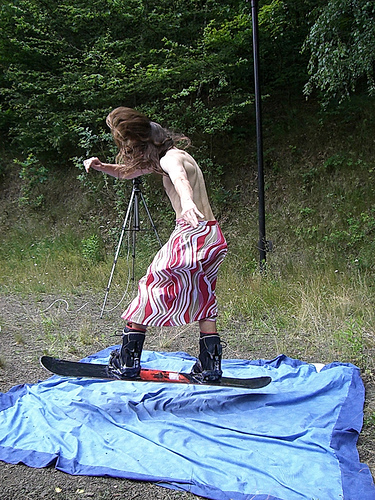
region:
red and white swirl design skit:
[134, 219, 231, 319]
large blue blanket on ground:
[8, 331, 369, 499]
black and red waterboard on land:
[39, 348, 271, 390]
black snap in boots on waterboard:
[109, 325, 229, 379]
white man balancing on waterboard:
[82, 103, 228, 386]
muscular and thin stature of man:
[80, 140, 222, 232]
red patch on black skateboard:
[139, 367, 188, 386]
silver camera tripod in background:
[96, 171, 166, 316]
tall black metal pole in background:
[246, 0, 277, 279]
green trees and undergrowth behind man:
[2, 0, 370, 342]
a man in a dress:
[64, 82, 373, 398]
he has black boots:
[12, 270, 291, 440]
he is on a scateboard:
[12, 304, 254, 428]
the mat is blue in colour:
[14, 303, 369, 499]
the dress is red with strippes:
[141, 196, 259, 346]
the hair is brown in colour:
[62, 79, 209, 196]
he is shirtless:
[122, 158, 228, 221]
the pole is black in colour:
[239, 2, 278, 251]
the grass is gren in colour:
[265, 258, 373, 297]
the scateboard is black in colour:
[32, 323, 282, 412]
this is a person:
[78, 103, 237, 392]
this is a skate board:
[28, 308, 311, 444]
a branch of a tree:
[174, 98, 244, 147]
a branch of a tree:
[50, 112, 106, 160]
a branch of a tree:
[15, 96, 64, 162]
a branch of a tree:
[300, 77, 348, 107]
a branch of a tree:
[336, 189, 374, 249]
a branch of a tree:
[19, 14, 95, 81]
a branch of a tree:
[90, 48, 170, 113]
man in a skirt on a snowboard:
[41, 105, 271, 386]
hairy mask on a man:
[107, 109, 188, 175]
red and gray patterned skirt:
[114, 218, 223, 324]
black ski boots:
[108, 332, 222, 380]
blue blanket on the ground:
[2, 346, 370, 496]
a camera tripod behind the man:
[99, 175, 163, 319]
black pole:
[250, 3, 268, 273]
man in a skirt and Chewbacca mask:
[82, 115, 222, 382]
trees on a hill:
[6, 1, 366, 182]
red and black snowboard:
[40, 354, 269, 388]